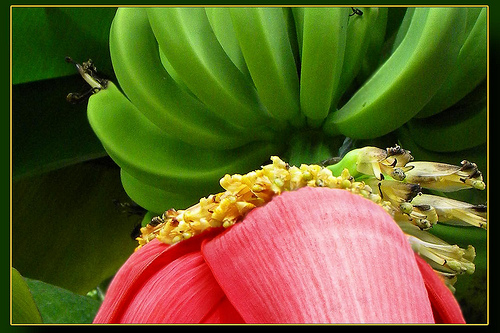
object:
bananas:
[66, 8, 488, 294]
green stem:
[263, 117, 345, 165]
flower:
[131, 144, 490, 291]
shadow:
[30, 8, 102, 81]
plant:
[93, 145, 489, 326]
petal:
[134, 145, 489, 294]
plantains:
[71, 6, 486, 325]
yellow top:
[133, 146, 488, 295]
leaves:
[92, 186, 468, 322]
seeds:
[136, 156, 393, 246]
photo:
[0, 0, 499, 329]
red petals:
[92, 186, 467, 327]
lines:
[288, 247, 377, 322]